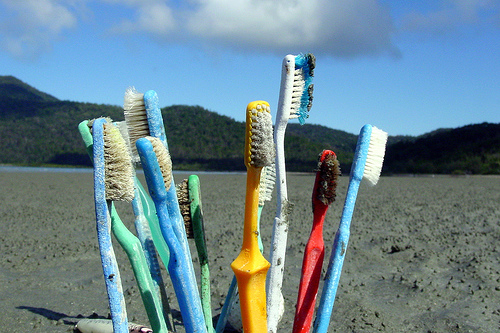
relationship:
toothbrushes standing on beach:
[78, 50, 388, 329] [1, 164, 498, 329]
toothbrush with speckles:
[87, 115, 142, 323] [107, 253, 124, 320]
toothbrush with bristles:
[231, 100, 277, 329] [251, 105, 276, 173]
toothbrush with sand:
[269, 53, 318, 326] [306, 53, 313, 101]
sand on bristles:
[306, 53, 313, 101] [288, 52, 312, 121]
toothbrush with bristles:
[290, 147, 339, 330] [316, 153, 337, 203]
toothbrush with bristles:
[315, 127, 393, 329] [359, 125, 389, 184]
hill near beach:
[1, 77, 496, 169] [1, 164, 498, 329]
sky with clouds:
[1, 0, 494, 138] [398, 0, 498, 48]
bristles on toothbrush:
[250, 103, 280, 171] [233, 100, 273, 327]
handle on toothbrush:
[230, 170, 273, 330] [231, 100, 277, 329]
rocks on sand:
[386, 242, 419, 294] [0, 163, 494, 329]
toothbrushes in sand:
[78, 50, 388, 329] [0, 163, 494, 329]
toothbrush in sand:
[232, 94, 288, 330] [0, 163, 494, 329]